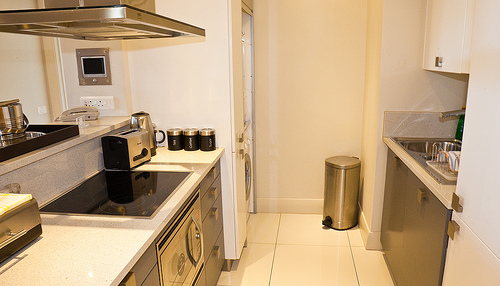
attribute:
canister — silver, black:
[166, 128, 183, 151]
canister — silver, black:
[184, 128, 199, 151]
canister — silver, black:
[198, 128, 217, 152]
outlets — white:
[83, 95, 117, 110]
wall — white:
[1, 1, 133, 117]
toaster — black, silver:
[100, 127, 153, 171]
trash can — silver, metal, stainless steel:
[321, 154, 362, 231]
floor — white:
[212, 210, 394, 285]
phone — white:
[55, 105, 101, 122]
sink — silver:
[389, 135, 463, 157]